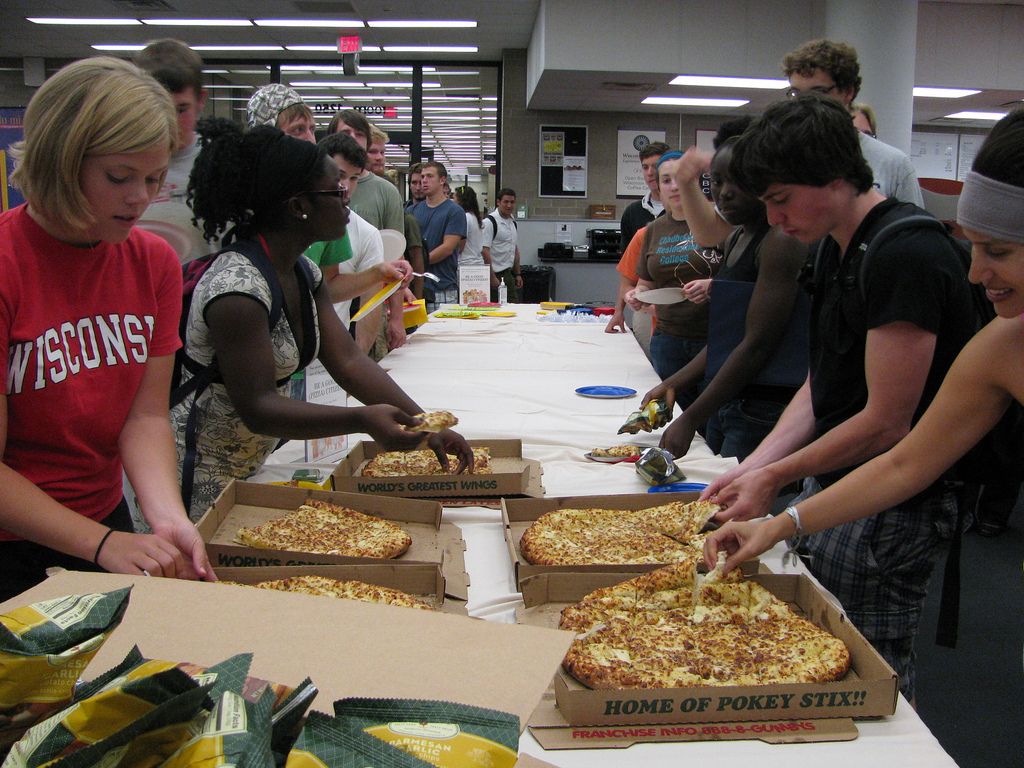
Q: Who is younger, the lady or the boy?
A: The boy is younger than the lady.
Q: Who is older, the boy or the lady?
A: The lady is older than the boy.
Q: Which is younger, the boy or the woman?
A: The boy is younger than the woman.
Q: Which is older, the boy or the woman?
A: The woman is older than the boy.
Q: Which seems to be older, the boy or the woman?
A: The woman is older than the boy.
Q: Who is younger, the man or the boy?
A: The boy is younger than the man.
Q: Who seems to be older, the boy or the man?
A: The man is older than the boy.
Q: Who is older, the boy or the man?
A: The man is older than the boy.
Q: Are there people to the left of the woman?
A: Yes, there is a person to the left of the woman.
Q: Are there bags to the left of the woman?
A: No, there is a person to the left of the woman.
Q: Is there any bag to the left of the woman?
A: No, there is a person to the left of the woman.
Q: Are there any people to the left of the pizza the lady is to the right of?
A: Yes, there is a person to the left of the pizza.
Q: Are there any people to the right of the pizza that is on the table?
A: No, the person is to the left of the pizza.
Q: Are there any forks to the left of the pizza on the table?
A: No, there is a person to the left of the pizza.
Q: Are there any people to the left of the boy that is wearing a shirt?
A: Yes, there is a person to the left of the boy.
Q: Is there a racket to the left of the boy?
A: No, there is a person to the left of the boy.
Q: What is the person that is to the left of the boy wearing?
A: The person is wearing a shirt.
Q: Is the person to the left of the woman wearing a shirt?
A: Yes, the person is wearing a shirt.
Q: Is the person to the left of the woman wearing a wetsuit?
A: No, the person is wearing a shirt.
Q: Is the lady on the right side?
A: Yes, the lady is on the right of the image.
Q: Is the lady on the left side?
A: No, the lady is on the right of the image.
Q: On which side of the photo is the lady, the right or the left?
A: The lady is on the right of the image.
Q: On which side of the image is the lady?
A: The lady is on the right of the image.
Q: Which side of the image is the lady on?
A: The lady is on the right of the image.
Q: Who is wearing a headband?
A: The lady is wearing a headband.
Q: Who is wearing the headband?
A: The lady is wearing a headband.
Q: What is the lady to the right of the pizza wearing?
A: The lady is wearing a hair band.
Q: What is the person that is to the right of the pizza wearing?
A: The lady is wearing a hair band.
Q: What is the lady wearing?
A: The lady is wearing a hair band.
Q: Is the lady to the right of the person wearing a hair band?
A: Yes, the lady is wearing a hair band.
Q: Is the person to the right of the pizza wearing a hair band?
A: Yes, the lady is wearing a hair band.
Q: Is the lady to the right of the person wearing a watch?
A: No, the lady is wearing a hair band.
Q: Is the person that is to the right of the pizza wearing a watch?
A: No, the lady is wearing a hair band.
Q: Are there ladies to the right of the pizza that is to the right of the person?
A: Yes, there is a lady to the right of the pizza.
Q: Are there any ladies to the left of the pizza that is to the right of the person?
A: No, the lady is to the right of the pizza.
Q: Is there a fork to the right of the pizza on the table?
A: No, there is a lady to the right of the pizza.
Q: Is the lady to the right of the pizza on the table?
A: Yes, the lady is to the right of the pizza.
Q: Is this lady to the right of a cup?
A: No, the lady is to the right of the pizza.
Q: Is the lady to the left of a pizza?
A: No, the lady is to the right of a pizza.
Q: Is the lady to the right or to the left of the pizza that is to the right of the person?
A: The lady is to the right of the pizza.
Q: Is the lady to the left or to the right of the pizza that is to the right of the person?
A: The lady is to the right of the pizza.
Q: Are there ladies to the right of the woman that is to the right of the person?
A: Yes, there is a lady to the right of the woman.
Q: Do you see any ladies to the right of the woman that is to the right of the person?
A: Yes, there is a lady to the right of the woman.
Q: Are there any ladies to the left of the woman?
A: No, the lady is to the right of the woman.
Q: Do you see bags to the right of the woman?
A: No, there is a lady to the right of the woman.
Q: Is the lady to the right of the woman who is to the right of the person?
A: Yes, the lady is to the right of the woman.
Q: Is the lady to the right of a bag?
A: No, the lady is to the right of the woman.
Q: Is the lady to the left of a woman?
A: No, the lady is to the right of a woman.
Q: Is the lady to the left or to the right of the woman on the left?
A: The lady is to the right of the woman.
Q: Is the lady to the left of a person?
A: No, the lady is to the right of a person.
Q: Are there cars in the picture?
A: No, there are no cars.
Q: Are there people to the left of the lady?
A: Yes, there is a person to the left of the lady.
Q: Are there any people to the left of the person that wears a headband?
A: Yes, there is a person to the left of the lady.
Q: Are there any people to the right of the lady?
A: No, the person is to the left of the lady.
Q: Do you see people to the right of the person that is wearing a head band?
A: No, the person is to the left of the lady.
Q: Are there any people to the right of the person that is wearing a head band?
A: No, the person is to the left of the lady.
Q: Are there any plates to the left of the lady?
A: No, there is a person to the left of the lady.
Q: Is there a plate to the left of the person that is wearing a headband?
A: No, there is a person to the left of the lady.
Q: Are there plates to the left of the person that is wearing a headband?
A: No, there is a person to the left of the lady.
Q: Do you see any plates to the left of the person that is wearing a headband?
A: No, there is a person to the left of the lady.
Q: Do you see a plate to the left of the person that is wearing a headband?
A: No, there is a person to the left of the lady.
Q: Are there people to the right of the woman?
A: Yes, there is a person to the right of the woman.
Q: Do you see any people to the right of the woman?
A: Yes, there is a person to the right of the woman.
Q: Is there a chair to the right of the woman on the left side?
A: No, there is a person to the right of the woman.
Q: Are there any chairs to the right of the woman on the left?
A: No, there is a person to the right of the woman.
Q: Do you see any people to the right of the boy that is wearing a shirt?
A: Yes, there is a person to the right of the boy.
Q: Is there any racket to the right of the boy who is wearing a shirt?
A: No, there is a person to the right of the boy.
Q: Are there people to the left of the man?
A: Yes, there is a person to the left of the man.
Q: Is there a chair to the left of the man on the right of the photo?
A: No, there is a person to the left of the man.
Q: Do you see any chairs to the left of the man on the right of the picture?
A: No, there is a person to the left of the man.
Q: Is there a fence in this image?
A: No, there are no fences.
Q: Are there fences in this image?
A: No, there are no fences.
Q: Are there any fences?
A: No, there are no fences.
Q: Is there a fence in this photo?
A: No, there are no fences.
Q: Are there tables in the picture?
A: Yes, there is a table.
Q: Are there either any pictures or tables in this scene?
A: Yes, there is a table.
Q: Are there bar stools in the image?
A: No, there are no bar stools.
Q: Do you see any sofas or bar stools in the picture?
A: No, there are no bar stools or sofas.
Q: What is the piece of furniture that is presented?
A: The piece of furniture is a table.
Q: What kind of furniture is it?
A: The piece of furniture is a table.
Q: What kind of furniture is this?
A: This is a table.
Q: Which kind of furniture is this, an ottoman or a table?
A: This is a table.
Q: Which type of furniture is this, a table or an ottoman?
A: This is a table.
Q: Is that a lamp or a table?
A: That is a table.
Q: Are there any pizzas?
A: Yes, there is a pizza.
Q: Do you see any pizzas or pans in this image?
A: Yes, there is a pizza.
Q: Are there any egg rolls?
A: No, there are no egg rolls.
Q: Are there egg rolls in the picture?
A: No, there are no egg rolls.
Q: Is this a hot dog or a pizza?
A: This is a pizza.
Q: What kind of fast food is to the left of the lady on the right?
A: The food is a pizza.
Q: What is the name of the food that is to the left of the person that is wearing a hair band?
A: The food is a pizza.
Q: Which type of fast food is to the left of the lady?
A: The food is a pizza.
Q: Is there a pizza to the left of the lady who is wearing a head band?
A: Yes, there is a pizza to the left of the lady.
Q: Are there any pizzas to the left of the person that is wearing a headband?
A: Yes, there is a pizza to the left of the lady.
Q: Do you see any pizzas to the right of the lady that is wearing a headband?
A: No, the pizza is to the left of the lady.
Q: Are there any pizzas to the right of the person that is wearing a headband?
A: No, the pizza is to the left of the lady.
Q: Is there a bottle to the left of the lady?
A: No, there is a pizza to the left of the lady.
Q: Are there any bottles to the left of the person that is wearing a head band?
A: No, there is a pizza to the left of the lady.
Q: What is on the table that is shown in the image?
A: The pizza is on the table.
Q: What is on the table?
A: The pizza is on the table.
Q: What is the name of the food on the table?
A: The food is a pizza.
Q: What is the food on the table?
A: The food is a pizza.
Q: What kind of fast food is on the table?
A: The food is a pizza.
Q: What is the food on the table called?
A: The food is a pizza.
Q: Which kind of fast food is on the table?
A: The food is a pizza.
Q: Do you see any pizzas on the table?
A: Yes, there is a pizza on the table.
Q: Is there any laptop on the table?
A: No, there is a pizza on the table.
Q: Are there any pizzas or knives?
A: Yes, there is a pizza.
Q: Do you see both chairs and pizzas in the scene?
A: No, there is a pizza but no chairs.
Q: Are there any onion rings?
A: No, there are no onion rings.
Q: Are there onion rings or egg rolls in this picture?
A: No, there are no onion rings or egg rolls.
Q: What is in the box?
A: The pizza is in the box.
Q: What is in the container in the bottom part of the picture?
A: The pizza is in the box.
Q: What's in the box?
A: The pizza is in the box.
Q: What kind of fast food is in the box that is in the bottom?
A: The food is a pizza.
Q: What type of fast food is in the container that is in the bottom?
A: The food is a pizza.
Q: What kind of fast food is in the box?
A: The food is a pizza.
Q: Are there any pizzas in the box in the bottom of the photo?
A: Yes, there is a pizza in the box.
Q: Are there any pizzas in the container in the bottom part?
A: Yes, there is a pizza in the box.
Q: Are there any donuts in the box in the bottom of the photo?
A: No, there is a pizza in the box.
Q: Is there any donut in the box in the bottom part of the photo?
A: No, there is a pizza in the box.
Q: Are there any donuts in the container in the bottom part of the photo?
A: No, there is a pizza in the box.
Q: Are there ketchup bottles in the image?
A: No, there are no ketchup bottles.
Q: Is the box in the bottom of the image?
A: Yes, the box is in the bottom of the image.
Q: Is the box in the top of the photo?
A: No, the box is in the bottom of the image.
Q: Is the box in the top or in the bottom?
A: The box is in the bottom of the image.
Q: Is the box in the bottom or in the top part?
A: The box is in the bottom of the image.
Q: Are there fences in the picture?
A: No, there are no fences.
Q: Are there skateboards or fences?
A: No, there are no fences or skateboards.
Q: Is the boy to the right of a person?
A: No, the boy is to the left of a person.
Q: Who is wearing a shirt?
A: The boy is wearing a shirt.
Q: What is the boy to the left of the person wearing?
A: The boy is wearing a shirt.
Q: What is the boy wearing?
A: The boy is wearing a shirt.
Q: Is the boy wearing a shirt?
A: Yes, the boy is wearing a shirt.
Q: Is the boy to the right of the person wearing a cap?
A: No, the boy is wearing a shirt.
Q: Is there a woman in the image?
A: Yes, there is a woman.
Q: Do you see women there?
A: Yes, there is a woman.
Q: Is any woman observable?
A: Yes, there is a woman.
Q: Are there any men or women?
A: Yes, there is a woman.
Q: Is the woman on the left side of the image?
A: Yes, the woman is on the left of the image.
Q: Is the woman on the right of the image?
A: No, the woman is on the left of the image.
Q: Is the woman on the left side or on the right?
A: The woman is on the left of the image.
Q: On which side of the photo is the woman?
A: The woman is on the left of the image.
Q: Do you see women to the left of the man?
A: Yes, there is a woman to the left of the man.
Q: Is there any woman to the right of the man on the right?
A: No, the woman is to the left of the man.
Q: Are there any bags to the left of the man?
A: No, there is a woman to the left of the man.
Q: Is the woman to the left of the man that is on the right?
A: Yes, the woman is to the left of the man.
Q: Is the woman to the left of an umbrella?
A: No, the woman is to the left of the man.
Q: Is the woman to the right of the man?
A: No, the woman is to the left of the man.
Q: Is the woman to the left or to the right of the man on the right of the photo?
A: The woman is to the left of the man.